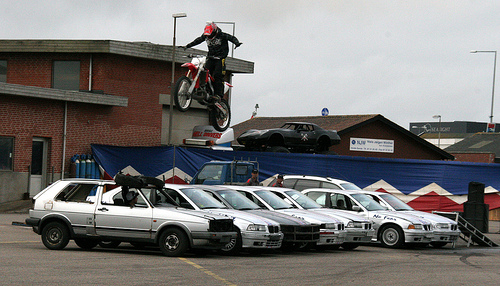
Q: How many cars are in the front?
A: Seven.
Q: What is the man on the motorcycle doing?
A: Tricks.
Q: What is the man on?
A: Motorcycle.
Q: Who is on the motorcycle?
A: Man.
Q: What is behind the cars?
A: Building.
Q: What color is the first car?
A: Gray.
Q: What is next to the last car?
A: Ramp.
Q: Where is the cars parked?
A: Lot.